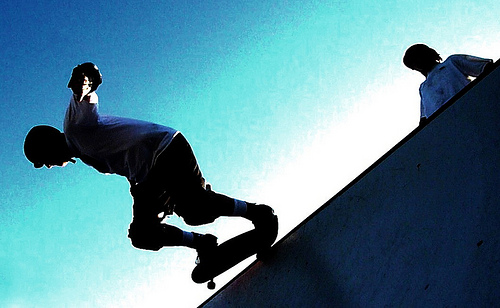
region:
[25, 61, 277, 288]
man wearing dark helmet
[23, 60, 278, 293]
man wearing white t-shirt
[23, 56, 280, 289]
skater wearing dark shorts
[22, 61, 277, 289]
man doing trick on skateboard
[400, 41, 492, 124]
man watching skateboarder doing trick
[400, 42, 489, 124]
man wearing dark helmet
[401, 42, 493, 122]
man wearing white t-shirt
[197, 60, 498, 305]
tall gray skating ramp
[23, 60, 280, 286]
skater doing trick on ramp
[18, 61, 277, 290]
skateboarder with arm raised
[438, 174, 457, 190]
part of a wall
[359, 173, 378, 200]
edge of a wall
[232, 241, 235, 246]
part of a board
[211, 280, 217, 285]
part of a wheel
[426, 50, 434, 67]
face of a boy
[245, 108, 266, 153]
part of the sky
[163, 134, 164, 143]
part of a shirt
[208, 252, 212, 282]
part of a board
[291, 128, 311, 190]
part of the cloud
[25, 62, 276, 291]
A skateboarder doing a trick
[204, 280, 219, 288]
The wheel of the skateboard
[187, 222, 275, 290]
The silohette of the skateboard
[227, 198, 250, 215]
A white sock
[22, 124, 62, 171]
A helmet on the skateboarder's head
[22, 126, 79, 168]
The skateboarder's face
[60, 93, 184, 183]
A white shirt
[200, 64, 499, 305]
A cement ramp in a skatepark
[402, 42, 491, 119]
A person watching the skateboarder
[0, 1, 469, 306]
A bright blue sky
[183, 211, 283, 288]
Person on a skate board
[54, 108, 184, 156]
Man wearing a tee shirt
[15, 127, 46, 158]
person with a helmet on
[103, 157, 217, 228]
person wearing black shorts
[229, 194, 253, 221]
person wearing white socks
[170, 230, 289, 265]
person doing a trick on the skateboard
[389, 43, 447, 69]
Man with a hat on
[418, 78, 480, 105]
man wearing a white tee shirt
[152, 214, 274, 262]
Man in a skate park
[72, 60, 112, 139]
Man with his arms out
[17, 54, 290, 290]
skateboarder on a halfpipe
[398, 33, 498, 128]
skateboarder standing on top of halfpipe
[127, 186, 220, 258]
kneepads of the skateboarder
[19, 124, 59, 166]
helmet of the skateboarder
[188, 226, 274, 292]
skateboard with two wheels up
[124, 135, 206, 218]
shorts of the skateboarder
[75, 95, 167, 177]
short sleeve shirt of skateboarder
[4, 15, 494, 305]
blue and white sky above ramp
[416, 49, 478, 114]
white shirt of man standing on top of ramp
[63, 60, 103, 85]
elbow pad of skateboarder